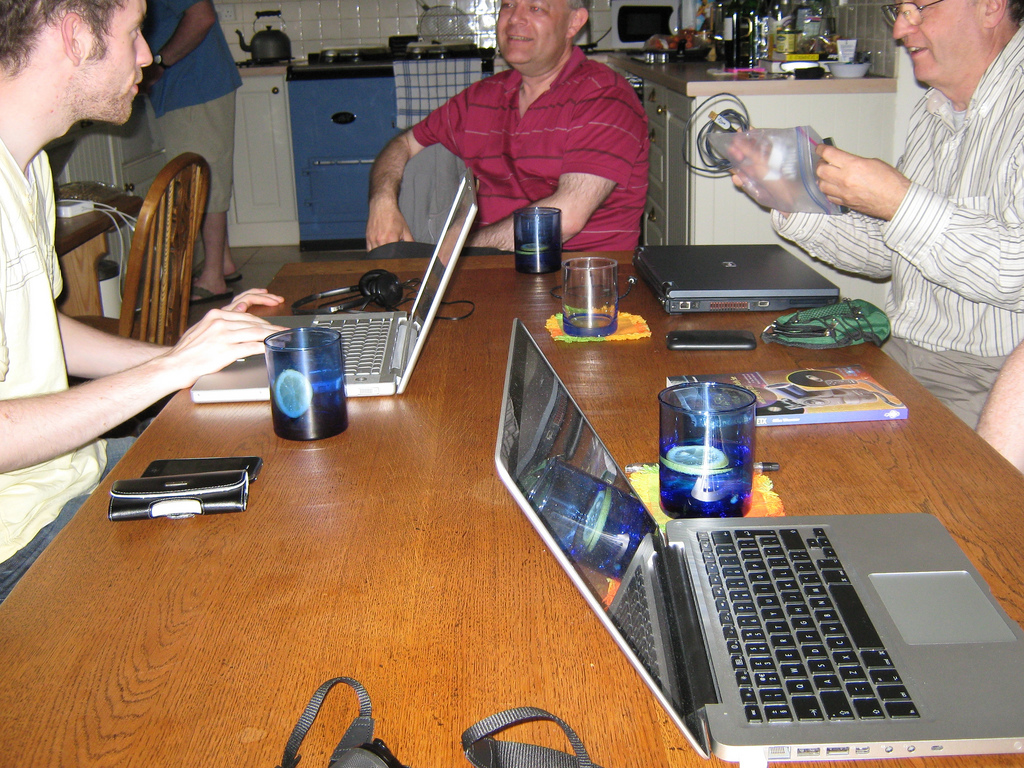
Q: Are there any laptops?
A: Yes, there is a laptop.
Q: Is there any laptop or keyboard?
A: Yes, there is a laptop.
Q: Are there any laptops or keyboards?
A: Yes, there is a laptop.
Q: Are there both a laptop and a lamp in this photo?
A: No, there is a laptop but no lamps.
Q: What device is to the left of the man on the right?
A: The device is a laptop.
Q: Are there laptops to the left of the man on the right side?
A: Yes, there is a laptop to the left of the man.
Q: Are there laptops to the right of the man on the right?
A: No, the laptop is to the left of the man.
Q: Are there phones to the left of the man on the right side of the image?
A: No, there is a laptop to the left of the man.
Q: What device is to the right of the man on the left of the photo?
A: The device is a laptop.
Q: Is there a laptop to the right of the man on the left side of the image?
A: Yes, there is a laptop to the right of the man.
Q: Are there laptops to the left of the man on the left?
A: No, the laptop is to the right of the man.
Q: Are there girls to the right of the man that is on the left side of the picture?
A: No, there is a laptop to the right of the man.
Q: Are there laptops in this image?
A: Yes, there is a laptop.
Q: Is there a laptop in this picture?
A: Yes, there is a laptop.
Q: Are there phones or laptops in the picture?
A: Yes, there is a laptop.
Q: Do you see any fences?
A: No, there are no fences.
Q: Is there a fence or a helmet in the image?
A: No, there are no fences or helmets.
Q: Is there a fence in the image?
A: No, there are no fences.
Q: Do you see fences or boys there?
A: No, there are no fences or boys.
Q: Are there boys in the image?
A: No, there are no boys.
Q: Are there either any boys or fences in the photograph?
A: No, there are no boys or fences.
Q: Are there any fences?
A: No, there are no fences.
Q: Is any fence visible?
A: No, there are no fences.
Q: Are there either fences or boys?
A: No, there are no fences or boys.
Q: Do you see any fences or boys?
A: No, there are no fences or boys.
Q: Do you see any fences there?
A: No, there are no fences.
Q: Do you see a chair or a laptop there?
A: Yes, there is a laptop.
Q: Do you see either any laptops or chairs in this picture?
A: Yes, there is a laptop.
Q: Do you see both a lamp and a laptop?
A: No, there is a laptop but no lamps.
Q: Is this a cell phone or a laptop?
A: This is a laptop.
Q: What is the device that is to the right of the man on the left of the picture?
A: The device is a laptop.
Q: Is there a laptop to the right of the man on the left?
A: Yes, there is a laptop to the right of the man.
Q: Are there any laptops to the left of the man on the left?
A: No, the laptop is to the right of the man.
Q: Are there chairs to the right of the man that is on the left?
A: No, there is a laptop to the right of the man.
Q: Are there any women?
A: No, there are no women.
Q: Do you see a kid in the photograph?
A: No, there are no children.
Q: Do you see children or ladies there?
A: No, there are no children or ladies.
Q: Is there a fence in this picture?
A: No, there are no fences.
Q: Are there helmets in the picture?
A: No, there are no helmets.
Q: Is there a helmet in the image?
A: No, there are no helmets.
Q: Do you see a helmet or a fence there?
A: No, there are no helmets or fences.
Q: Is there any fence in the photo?
A: No, there are no fences.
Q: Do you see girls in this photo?
A: No, there are no girls.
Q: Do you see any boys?
A: No, there are no boys.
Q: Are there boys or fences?
A: No, there are no boys or fences.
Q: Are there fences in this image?
A: No, there are no fences.